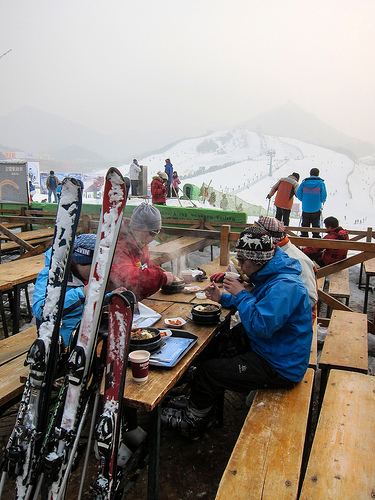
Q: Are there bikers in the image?
A: No, there are no bikers.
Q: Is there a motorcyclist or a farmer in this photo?
A: No, there are no bikers or farmers.